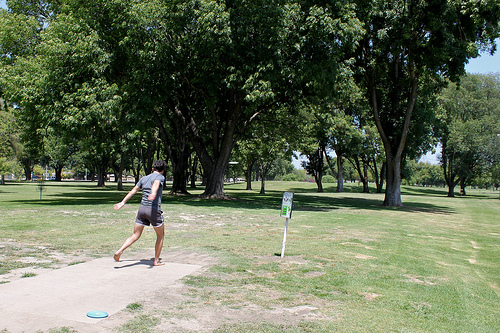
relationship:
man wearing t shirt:
[111, 157, 167, 265] [136, 170, 166, 205]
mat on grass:
[0, 252, 203, 327] [1, 175, 498, 329]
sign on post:
[278, 190, 293, 219] [280, 220, 292, 256]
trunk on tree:
[379, 140, 404, 212] [306, 0, 497, 207]